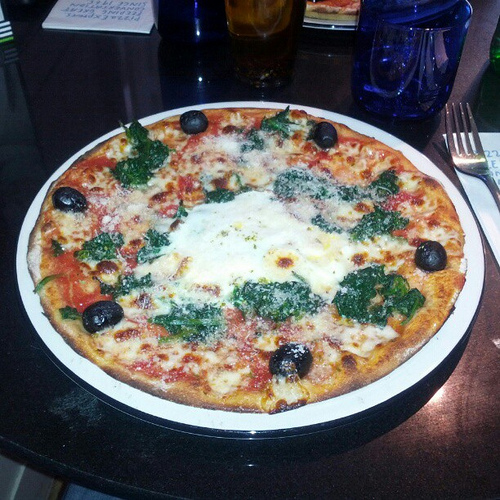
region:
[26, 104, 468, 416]
Pizza on a plate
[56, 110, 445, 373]
Black olives on pizza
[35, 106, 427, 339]
green vegetables on pizza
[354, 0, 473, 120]
blue glass drinking cup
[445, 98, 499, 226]
Fork is right of pizza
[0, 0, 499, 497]
Black table top under plate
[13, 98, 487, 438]
White plate under pizza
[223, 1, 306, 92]
brown glass with ice in it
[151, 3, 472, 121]
Three glasses behind pizza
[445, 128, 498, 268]
Napkin under fork to right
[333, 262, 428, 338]
dark green vegetables atop pizza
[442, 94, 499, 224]
shiny fork on table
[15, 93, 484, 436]
round pizza on white plate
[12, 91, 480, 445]
round pizza with large black olives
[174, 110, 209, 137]
one large black olive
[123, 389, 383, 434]
white edge of round plate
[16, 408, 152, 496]
edge of curved dark table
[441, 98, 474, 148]
four long fork tines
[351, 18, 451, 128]
shiny dark blue glass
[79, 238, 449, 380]
three black olives on pizza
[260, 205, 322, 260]
part of some ash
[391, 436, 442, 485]
part of a table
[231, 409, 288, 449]
edge of a plate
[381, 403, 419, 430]
edge of a shade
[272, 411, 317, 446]
part of a plate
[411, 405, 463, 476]
part of a table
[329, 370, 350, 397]
edge of a pizza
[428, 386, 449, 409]
part of some light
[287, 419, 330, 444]
edge of a plate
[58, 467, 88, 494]
edge of a plate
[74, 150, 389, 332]
this is a pizza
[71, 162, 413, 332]
the pizza is big in size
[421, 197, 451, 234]
the pizza is yellow in color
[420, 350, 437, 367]
part of a plate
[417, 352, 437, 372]
the plate is flat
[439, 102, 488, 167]
this is a fork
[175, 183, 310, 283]
milk is poured in the middle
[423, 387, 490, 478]
this is the table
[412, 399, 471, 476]
the table is wooden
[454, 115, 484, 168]
fork is shiny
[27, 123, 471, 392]
pizza placed on white plate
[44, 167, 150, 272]
black olive on top of pizza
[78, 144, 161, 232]
cheese sprinkled on pizza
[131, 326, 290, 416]
tomato sauce on pizza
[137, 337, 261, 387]
golden cheese melted on pizza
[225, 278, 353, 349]
green vegetable on top of pizza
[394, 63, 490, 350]
fork on paper next to plate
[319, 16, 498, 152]
glass on table near fork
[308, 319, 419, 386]
pizza edge is brown crust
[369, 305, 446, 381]
touch of flour on edge of pizza crust